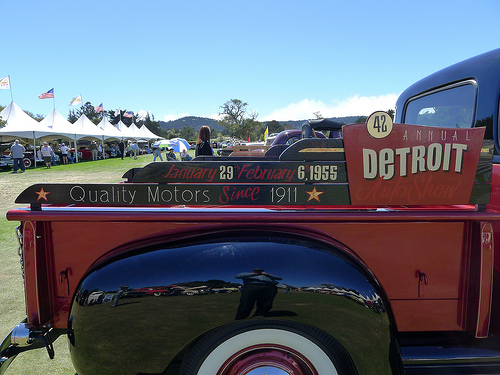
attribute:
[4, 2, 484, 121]
sky — blue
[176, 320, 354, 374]
tire — white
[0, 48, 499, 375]
truck — black, red, shiny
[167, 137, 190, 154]
umbrella — blue, white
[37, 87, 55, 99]
usa flag — waving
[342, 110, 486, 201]
sign — red, white, gold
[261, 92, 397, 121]
clouds — white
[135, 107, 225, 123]
clouds — white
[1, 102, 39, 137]
roof — white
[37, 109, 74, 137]
roof — white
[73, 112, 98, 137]
roof — white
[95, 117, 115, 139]
roof — white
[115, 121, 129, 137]
roof — white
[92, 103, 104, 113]
flag — waving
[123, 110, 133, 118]
flag — waving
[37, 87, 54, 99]
flag — waving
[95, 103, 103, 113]
usa flag — waving